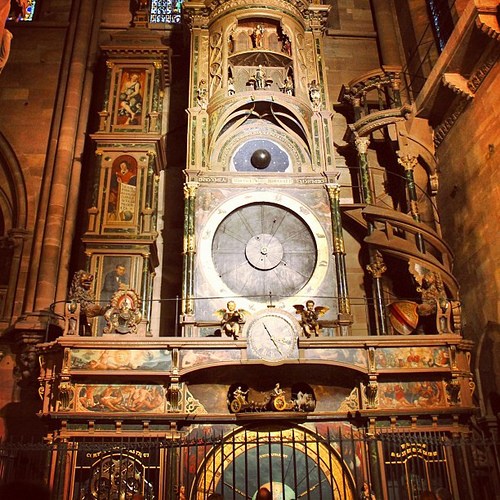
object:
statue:
[213, 299, 252, 340]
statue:
[243, 63, 272, 93]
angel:
[290, 301, 327, 339]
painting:
[111, 70, 147, 129]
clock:
[247, 315, 297, 363]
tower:
[180, 0, 355, 345]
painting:
[101, 153, 139, 222]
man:
[107, 159, 135, 214]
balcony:
[409, 0, 473, 118]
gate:
[0, 422, 499, 500]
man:
[99, 263, 127, 303]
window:
[150, 1, 182, 25]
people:
[271, 381, 286, 396]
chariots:
[228, 394, 312, 413]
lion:
[67, 269, 109, 335]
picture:
[0, 0, 499, 499]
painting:
[91, 253, 132, 337]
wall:
[0, 0, 438, 446]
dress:
[117, 82, 142, 117]